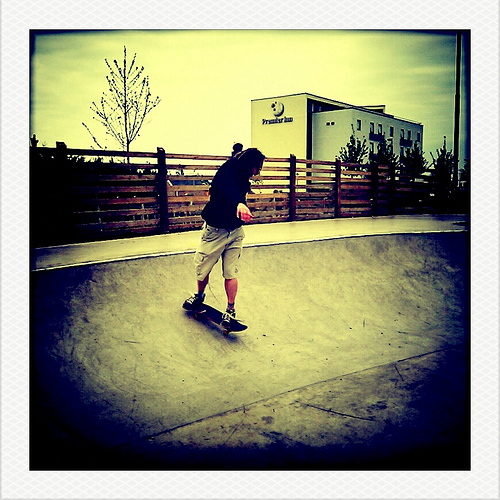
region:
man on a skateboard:
[172, 134, 277, 343]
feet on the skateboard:
[178, 294, 255, 344]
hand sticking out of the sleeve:
[233, 194, 263, 226]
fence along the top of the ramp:
[31, 135, 478, 245]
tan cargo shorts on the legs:
[186, 218, 246, 280]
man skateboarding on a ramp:
[176, 132, 299, 348]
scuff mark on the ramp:
[292, 395, 384, 425]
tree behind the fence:
[85, 48, 163, 183]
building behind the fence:
[240, 89, 448, 214]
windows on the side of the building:
[350, 113, 425, 143]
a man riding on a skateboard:
[181, 147, 266, 337]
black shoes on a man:
[182, 291, 239, 331]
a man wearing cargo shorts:
[188, 217, 246, 282]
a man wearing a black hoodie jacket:
[196, 151, 255, 233]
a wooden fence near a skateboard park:
[34, 141, 469, 248]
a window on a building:
[351, 117, 363, 131]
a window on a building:
[369, 118, 375, 135]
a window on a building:
[376, 121, 384, 135]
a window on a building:
[388, 122, 397, 139]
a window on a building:
[398, 127, 405, 139]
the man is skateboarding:
[151, 107, 355, 369]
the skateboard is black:
[159, 289, 271, 356]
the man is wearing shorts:
[140, 200, 272, 322]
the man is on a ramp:
[135, 138, 363, 398]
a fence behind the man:
[87, 143, 349, 222]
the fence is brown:
[94, 125, 307, 230]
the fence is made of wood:
[93, 138, 349, 211]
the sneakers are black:
[155, 291, 247, 336]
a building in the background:
[222, 75, 435, 184]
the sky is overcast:
[100, 32, 440, 182]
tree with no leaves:
[85, 48, 165, 153]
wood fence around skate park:
[40, 139, 417, 214]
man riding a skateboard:
[172, 133, 273, 348]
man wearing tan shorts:
[171, 134, 271, 341]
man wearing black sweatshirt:
[169, 117, 269, 347]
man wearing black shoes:
[155, 123, 273, 350]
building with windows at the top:
[233, 75, 430, 181]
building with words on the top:
[238, 79, 425, 191]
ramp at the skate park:
[42, 210, 458, 438]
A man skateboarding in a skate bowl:
[172, 140, 281, 348]